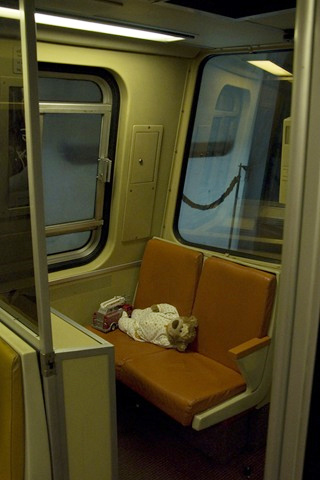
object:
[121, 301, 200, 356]
bear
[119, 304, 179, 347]
nightie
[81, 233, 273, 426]
seat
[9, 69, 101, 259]
window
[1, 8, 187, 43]
light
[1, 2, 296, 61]
ceiling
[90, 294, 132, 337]
toys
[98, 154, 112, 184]
handle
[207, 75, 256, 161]
reflection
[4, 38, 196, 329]
wall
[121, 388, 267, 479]
floor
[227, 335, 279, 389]
arm rest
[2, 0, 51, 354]
divider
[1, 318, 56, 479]
next seat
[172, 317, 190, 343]
face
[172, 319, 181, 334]
nose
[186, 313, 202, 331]
ear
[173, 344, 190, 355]
ear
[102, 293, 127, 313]
ladder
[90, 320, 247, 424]
cushion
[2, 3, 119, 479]
trim